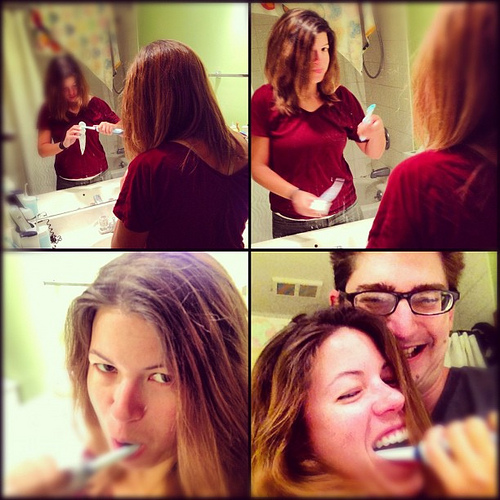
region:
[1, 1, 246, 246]
a reflection on the mirror of a girl brushing her teeth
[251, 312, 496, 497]
a girl brushing her teeth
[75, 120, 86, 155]
the toothpaste tube is white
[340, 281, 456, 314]
the man is wearing eye glasses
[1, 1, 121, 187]
a mirror with a reflection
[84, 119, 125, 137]
the girl is holding an electric toothbrush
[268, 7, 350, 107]
Girl with brown hair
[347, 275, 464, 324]
man wearing reading glasses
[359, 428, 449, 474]
toothbrush in girls mouth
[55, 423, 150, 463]
woman brushing her teeth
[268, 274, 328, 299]
vent on the ceiling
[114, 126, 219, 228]
woman wearing red shirt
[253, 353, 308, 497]
woman with blonde streaks in her hair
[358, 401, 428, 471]
woman with a big smile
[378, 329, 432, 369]
man with a big smile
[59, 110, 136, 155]
woman putting toothpaste on the brush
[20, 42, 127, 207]
this is a person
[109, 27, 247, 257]
this is a person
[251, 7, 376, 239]
this is a person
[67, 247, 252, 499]
this is a person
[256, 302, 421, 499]
this is a person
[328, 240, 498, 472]
this is a person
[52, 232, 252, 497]
the person is brushing their teeth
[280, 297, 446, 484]
the person is brushing their teeth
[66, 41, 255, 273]
the person is brushing their teeth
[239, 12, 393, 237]
the person is brushing their teeth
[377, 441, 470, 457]
A toothbrush in a woman's mouth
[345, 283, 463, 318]
Eyeglasses on a man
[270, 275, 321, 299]
A vent in a ceiling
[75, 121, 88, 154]
A tube of toothpaste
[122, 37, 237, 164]
Brown hair on a woman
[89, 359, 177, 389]
Brown eyes in a girl's face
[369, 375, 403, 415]
A nose on a girl's face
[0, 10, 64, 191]
A white shower curtain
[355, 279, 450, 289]
Thick eyebrows on a man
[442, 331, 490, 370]
Bunched white shower curtain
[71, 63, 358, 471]
this photo is split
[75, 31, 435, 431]
this is four photos in one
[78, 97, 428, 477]
these are people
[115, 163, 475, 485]
the woman is brushing her teeth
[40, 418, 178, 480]
this is a toothbrush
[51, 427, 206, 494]
the brush is white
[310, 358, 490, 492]
the woman is smiling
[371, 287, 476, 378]
the man is smiling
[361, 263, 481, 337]
the man has glasses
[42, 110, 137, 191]
this is a tube of toothpaste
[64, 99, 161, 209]
Girl putting toothpaste on toothbrush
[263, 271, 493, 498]
Girl taking funny picture with her male friend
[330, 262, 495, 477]
Man with black glasses is smiling for the camera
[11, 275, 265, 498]
Girl is staring at the camera with the toothbrush in her mouth